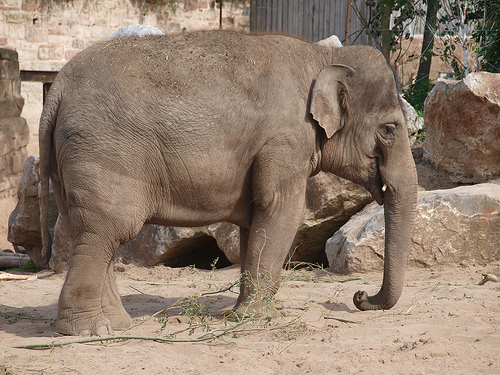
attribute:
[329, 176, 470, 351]
trunk — grey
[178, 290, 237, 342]
leaves — green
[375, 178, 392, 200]
tusk — small, white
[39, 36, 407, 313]
elephant — eye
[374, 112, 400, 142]
eye — brown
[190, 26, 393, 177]
elephant — gray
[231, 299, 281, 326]
hoof — brown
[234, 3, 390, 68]
fence — wooden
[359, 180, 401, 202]
tusk — white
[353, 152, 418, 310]
trunk — brown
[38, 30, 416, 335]
elephant — small, smaller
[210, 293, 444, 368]
sand — tan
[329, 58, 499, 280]
boulders — gray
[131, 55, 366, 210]
elephant — gray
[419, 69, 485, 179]
rock — tan, large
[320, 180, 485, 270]
rock — tan, large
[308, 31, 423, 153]
rock — tan, large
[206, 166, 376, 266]
rock — tan, large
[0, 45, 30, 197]
rock — tan, large